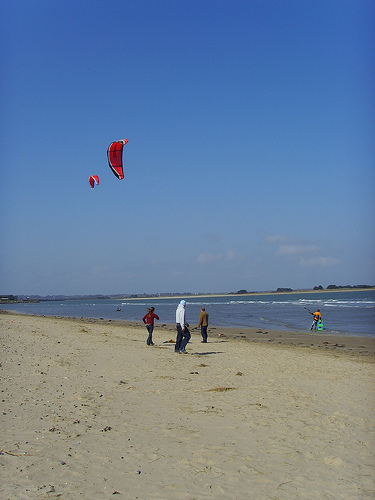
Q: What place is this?
A: It is a beach.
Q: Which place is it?
A: It is a beach.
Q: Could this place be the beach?
A: Yes, it is the beach.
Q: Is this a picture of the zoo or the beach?
A: It is showing the beach.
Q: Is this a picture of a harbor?
A: No, the picture is showing a beach.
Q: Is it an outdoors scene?
A: Yes, it is outdoors.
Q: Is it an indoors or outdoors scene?
A: It is outdoors.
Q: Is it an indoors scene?
A: No, it is outdoors.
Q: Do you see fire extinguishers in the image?
A: No, there are no fire extinguishers.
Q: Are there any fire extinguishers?
A: No, there are no fire extinguishers.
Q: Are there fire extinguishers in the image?
A: No, there are no fire extinguishers.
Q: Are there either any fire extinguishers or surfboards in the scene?
A: No, there are no fire extinguishers or surfboards.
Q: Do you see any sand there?
A: Yes, there is sand.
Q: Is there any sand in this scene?
A: Yes, there is sand.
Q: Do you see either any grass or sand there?
A: Yes, there is sand.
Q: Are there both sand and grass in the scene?
A: No, there is sand but no grass.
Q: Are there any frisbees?
A: No, there are no frisbees.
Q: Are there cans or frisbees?
A: No, there are no frisbees or cans.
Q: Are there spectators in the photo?
A: No, there are no spectators.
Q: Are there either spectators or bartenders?
A: No, there are no spectators or bartenders.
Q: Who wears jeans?
A: The boy wears jeans.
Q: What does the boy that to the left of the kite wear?
A: The boy wears jeans.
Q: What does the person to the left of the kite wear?
A: The boy wears jeans.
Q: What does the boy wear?
A: The boy wears jeans.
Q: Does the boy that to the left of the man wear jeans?
A: Yes, the boy wears jeans.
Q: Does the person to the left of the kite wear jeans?
A: Yes, the boy wears jeans.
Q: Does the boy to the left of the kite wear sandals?
A: No, the boy wears jeans.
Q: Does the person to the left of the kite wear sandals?
A: No, the boy wears jeans.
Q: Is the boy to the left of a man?
A: Yes, the boy is to the left of a man.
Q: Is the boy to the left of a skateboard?
A: No, the boy is to the left of a man.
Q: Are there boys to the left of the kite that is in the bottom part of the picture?
A: Yes, there is a boy to the left of the kite.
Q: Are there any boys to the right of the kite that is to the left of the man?
A: No, the boy is to the left of the kite.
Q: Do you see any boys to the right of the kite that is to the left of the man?
A: No, the boy is to the left of the kite.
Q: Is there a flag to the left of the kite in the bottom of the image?
A: No, there is a boy to the left of the kite.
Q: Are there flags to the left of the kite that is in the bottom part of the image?
A: No, there is a boy to the left of the kite.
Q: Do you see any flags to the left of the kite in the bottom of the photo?
A: No, there is a boy to the left of the kite.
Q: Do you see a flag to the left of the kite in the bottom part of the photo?
A: No, there is a boy to the left of the kite.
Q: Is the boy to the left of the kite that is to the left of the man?
A: Yes, the boy is to the left of the kite.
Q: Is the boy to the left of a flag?
A: No, the boy is to the left of the kite.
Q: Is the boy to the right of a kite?
A: No, the boy is to the left of a kite.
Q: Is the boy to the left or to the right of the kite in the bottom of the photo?
A: The boy is to the left of the kite.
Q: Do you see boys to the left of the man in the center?
A: Yes, there is a boy to the left of the man.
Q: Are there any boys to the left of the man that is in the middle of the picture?
A: Yes, there is a boy to the left of the man.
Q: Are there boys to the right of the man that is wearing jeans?
A: No, the boy is to the left of the man.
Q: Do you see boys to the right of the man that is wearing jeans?
A: No, the boy is to the left of the man.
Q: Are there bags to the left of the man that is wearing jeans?
A: No, there is a boy to the left of the man.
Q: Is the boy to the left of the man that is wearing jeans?
A: Yes, the boy is to the left of the man.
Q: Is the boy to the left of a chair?
A: No, the boy is to the left of the man.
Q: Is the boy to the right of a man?
A: No, the boy is to the left of a man.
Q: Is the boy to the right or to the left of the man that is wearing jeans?
A: The boy is to the left of the man.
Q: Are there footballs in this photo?
A: No, there are no footballs.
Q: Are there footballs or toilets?
A: No, there are no footballs or toilets.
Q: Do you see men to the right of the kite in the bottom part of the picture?
A: Yes, there is a man to the right of the kite.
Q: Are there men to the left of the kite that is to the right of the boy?
A: No, the man is to the right of the kite.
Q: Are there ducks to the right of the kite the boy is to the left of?
A: No, there is a man to the right of the kite.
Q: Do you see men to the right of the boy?
A: Yes, there is a man to the right of the boy.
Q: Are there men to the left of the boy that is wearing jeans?
A: No, the man is to the right of the boy.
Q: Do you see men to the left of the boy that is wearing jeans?
A: No, the man is to the right of the boy.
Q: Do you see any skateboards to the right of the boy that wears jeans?
A: No, there is a man to the right of the boy.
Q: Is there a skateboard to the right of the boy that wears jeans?
A: No, there is a man to the right of the boy.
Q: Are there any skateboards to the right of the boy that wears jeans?
A: No, there is a man to the right of the boy.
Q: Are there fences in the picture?
A: No, there are no fences.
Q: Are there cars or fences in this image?
A: No, there are no fences or cars.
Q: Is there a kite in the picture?
A: Yes, there is a kite.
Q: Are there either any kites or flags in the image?
A: Yes, there is a kite.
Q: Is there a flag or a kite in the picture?
A: Yes, there is a kite.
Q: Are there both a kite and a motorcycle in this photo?
A: No, there is a kite but no motorcycles.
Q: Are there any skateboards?
A: No, there are no skateboards.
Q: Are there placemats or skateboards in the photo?
A: No, there are no skateboards or placemats.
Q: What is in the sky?
A: The kite is in the sky.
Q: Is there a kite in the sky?
A: Yes, there is a kite in the sky.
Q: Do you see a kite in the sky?
A: Yes, there is a kite in the sky.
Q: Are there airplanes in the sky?
A: No, there is a kite in the sky.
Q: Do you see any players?
A: No, there are no players.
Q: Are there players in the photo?
A: No, there are no players.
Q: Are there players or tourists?
A: No, there are no players or tourists.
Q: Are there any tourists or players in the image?
A: No, there are no players or tourists.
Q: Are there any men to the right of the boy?
A: Yes, there is a man to the right of the boy.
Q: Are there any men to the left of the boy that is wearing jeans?
A: No, the man is to the right of the boy.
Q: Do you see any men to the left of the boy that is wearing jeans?
A: No, the man is to the right of the boy.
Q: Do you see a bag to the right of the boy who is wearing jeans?
A: No, there is a man to the right of the boy.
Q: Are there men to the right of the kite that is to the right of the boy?
A: Yes, there is a man to the right of the kite.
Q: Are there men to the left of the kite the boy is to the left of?
A: No, the man is to the right of the kite.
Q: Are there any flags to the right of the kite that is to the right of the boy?
A: No, there is a man to the right of the kite.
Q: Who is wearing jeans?
A: The man is wearing jeans.